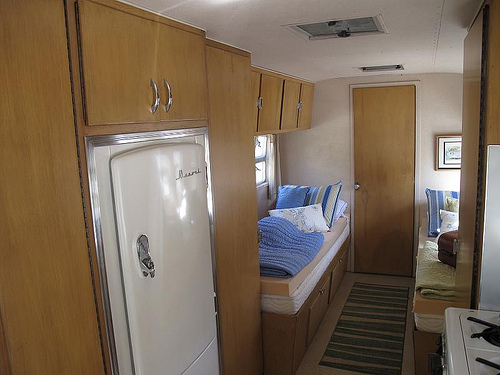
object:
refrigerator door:
[106, 146, 222, 368]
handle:
[135, 235, 157, 280]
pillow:
[267, 201, 331, 233]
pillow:
[276, 184, 311, 209]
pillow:
[306, 179, 345, 231]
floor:
[331, 265, 420, 367]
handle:
[150, 78, 161, 114]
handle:
[164, 78, 173, 113]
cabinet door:
[78, 2, 162, 124]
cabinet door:
[156, 22, 207, 124]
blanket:
[255, 215, 327, 278]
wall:
[423, 77, 483, 223]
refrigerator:
[102, 134, 227, 375]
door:
[350, 82, 415, 283]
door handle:
[354, 182, 361, 190]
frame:
[433, 134, 466, 172]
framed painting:
[433, 133, 465, 171]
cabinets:
[249, 60, 320, 136]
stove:
[434, 301, 495, 372]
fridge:
[86, 126, 218, 375]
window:
[254, 126, 277, 190]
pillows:
[425, 187, 459, 237]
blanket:
[413, 232, 456, 297]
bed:
[411, 213, 461, 332]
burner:
[466, 316, 497, 329]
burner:
[475, 355, 497, 371]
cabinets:
[68, 6, 212, 131]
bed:
[260, 181, 350, 317]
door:
[160, 17, 215, 128]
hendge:
[257, 95, 265, 109]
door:
[256, 70, 286, 136]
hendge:
[296, 101, 303, 108]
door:
[298, 79, 313, 127]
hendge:
[320, 288, 325, 294]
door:
[306, 273, 329, 343]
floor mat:
[318, 280, 411, 371]